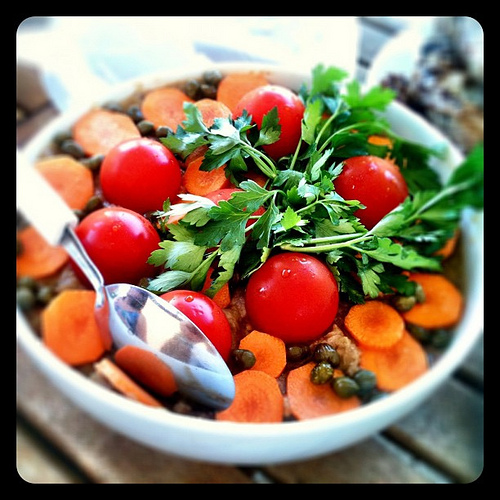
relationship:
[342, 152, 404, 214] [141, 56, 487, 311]
tomato under green leaves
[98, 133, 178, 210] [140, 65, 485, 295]
tomato under green leaves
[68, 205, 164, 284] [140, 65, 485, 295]
tomato under green leaves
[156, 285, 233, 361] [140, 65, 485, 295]
tomato under green leaves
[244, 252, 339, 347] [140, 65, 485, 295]
fruit under green leaves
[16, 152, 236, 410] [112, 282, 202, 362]
spoon reflecting some people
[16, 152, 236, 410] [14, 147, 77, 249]
spoon with handle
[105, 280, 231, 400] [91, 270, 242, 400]
reflection in spoon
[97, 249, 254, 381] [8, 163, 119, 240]
spoon has handle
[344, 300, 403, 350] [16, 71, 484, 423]
orange carrots in food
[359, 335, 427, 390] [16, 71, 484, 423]
vegetable in food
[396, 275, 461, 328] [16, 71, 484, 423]
vegetable in food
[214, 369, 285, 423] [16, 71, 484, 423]
vegetable in food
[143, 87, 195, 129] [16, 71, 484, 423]
vegetable in food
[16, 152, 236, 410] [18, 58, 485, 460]
spoon in bowl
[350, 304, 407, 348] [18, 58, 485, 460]
orange carrots in bowl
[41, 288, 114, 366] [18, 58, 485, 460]
carrot in bowl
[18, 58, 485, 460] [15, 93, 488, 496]
bowl on table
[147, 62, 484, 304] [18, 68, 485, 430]
green leaves on food